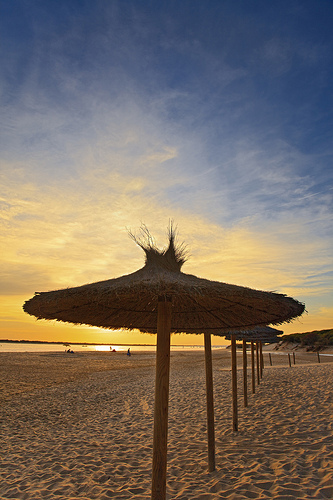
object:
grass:
[280, 328, 332, 352]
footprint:
[47, 482, 61, 490]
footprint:
[253, 481, 271, 491]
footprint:
[76, 454, 95, 462]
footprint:
[277, 479, 302, 483]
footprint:
[0, 482, 16, 497]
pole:
[230, 338, 240, 432]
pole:
[242, 333, 247, 409]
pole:
[268, 352, 273, 366]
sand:
[1, 350, 333, 500]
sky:
[0, 0, 332, 337]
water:
[0, 342, 225, 351]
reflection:
[93, 344, 120, 350]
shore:
[0, 345, 333, 500]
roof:
[41, 247, 297, 313]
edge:
[149, 414, 157, 443]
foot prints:
[223, 438, 327, 497]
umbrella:
[16, 214, 308, 498]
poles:
[151, 303, 174, 496]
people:
[127, 347, 131, 357]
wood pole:
[256, 337, 260, 387]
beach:
[0, 349, 333, 499]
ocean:
[1, 339, 229, 357]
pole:
[203, 333, 216, 475]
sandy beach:
[0, 326, 333, 500]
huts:
[24, 228, 304, 497]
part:
[67, 372, 113, 425]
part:
[116, 286, 144, 315]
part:
[9, 340, 21, 346]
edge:
[54, 283, 276, 303]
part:
[106, 432, 130, 474]